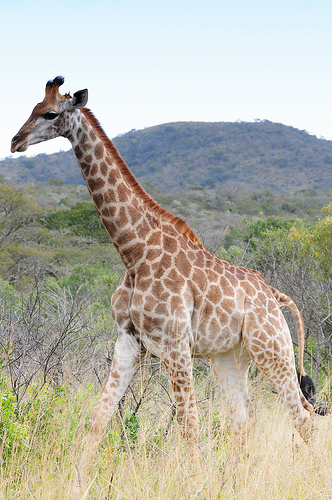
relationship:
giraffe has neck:
[10, 73, 331, 500] [68, 117, 186, 275]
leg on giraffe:
[75, 327, 155, 499] [10, 73, 331, 500]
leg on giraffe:
[164, 337, 209, 499] [10, 73, 331, 500]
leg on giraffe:
[214, 351, 261, 498] [10, 73, 331, 500]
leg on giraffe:
[243, 321, 331, 489] [10, 73, 331, 500]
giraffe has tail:
[10, 73, 331, 500] [271, 284, 318, 413]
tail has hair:
[271, 284, 318, 413] [295, 372, 318, 408]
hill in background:
[6, 117, 331, 197] [2, 65, 331, 266]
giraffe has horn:
[10, 73, 331, 500] [42, 79, 53, 103]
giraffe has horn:
[10, 73, 331, 500] [48, 74, 64, 99]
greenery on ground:
[2, 183, 330, 499] [7, 207, 331, 497]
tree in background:
[207, 178, 252, 213] [2, 65, 331, 266]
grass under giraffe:
[13, 386, 330, 499] [10, 73, 331, 500]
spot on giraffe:
[163, 267, 190, 295] [10, 73, 331, 500]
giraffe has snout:
[10, 73, 331, 500] [7, 130, 28, 155]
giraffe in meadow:
[10, 73, 331, 500] [0, 286, 330, 500]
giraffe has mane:
[10, 73, 331, 500] [82, 106, 203, 250]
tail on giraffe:
[271, 284, 318, 413] [10, 73, 331, 500]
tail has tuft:
[271, 284, 318, 413] [293, 363, 321, 408]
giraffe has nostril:
[10, 73, 331, 500] [12, 135, 20, 145]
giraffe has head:
[10, 73, 331, 500] [3, 73, 89, 155]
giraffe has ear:
[10, 73, 331, 500] [70, 82, 89, 114]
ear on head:
[70, 82, 89, 114] [3, 73, 89, 155]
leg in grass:
[164, 337, 209, 499] [13, 386, 330, 499]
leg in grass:
[75, 327, 155, 499] [13, 386, 330, 499]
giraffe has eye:
[10, 73, 331, 500] [41, 110, 60, 124]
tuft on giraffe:
[293, 363, 321, 408] [10, 73, 331, 500]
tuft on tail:
[293, 363, 321, 408] [271, 284, 318, 413]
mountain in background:
[6, 117, 331, 197] [2, 65, 331, 266]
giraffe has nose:
[10, 73, 331, 500] [8, 133, 23, 145]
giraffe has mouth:
[10, 73, 331, 500] [12, 140, 28, 152]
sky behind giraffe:
[2, 1, 331, 173] [10, 73, 331, 500]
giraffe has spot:
[10, 73, 331, 500] [163, 267, 190, 295]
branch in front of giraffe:
[121, 391, 157, 497] [10, 73, 331, 500]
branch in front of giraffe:
[41, 279, 96, 387] [10, 73, 331, 500]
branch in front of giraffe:
[102, 367, 157, 498] [10, 73, 331, 500]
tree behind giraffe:
[207, 178, 252, 213] [10, 73, 331, 500]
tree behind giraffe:
[186, 183, 204, 206] [10, 73, 331, 500]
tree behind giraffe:
[254, 188, 278, 217] [10, 73, 331, 500]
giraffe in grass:
[10, 73, 331, 500] [13, 386, 330, 499]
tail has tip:
[271, 284, 318, 413] [302, 371, 314, 407]